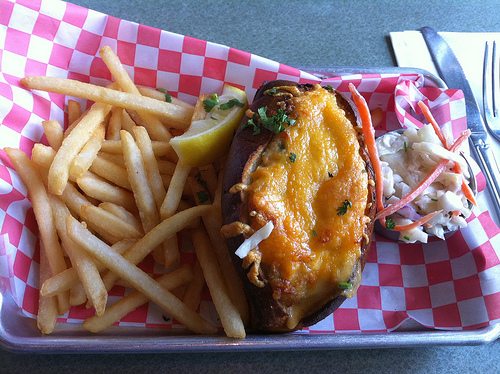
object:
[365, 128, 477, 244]
cup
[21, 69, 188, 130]
fry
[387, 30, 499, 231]
paper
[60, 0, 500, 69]
ground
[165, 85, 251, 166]
lemon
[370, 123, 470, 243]
food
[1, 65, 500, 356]
basket